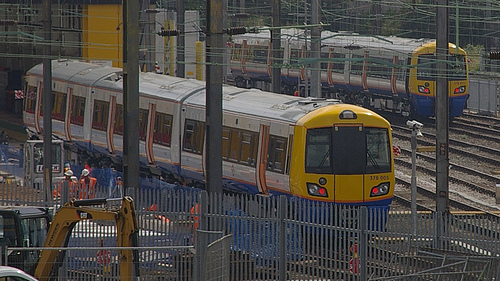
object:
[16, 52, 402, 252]
train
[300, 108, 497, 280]
tracks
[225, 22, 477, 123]
train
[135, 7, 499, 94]
background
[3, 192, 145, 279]
excavator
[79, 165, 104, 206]
men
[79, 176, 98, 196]
vest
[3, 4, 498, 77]
electric wires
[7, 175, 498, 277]
fence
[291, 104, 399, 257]
front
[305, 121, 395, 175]
windshield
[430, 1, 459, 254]
post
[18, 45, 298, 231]
grey cars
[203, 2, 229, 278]
bar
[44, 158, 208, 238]
people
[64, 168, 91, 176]
hard hats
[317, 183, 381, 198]
red headlights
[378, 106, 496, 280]
track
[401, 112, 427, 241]
cameras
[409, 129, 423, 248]
pole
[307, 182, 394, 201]
headlights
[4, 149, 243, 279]
trainyard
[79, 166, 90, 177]
hat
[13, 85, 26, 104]
sign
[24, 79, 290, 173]
windows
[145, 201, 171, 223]
worker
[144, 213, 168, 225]
safety vest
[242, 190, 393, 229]
bottom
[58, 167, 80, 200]
worker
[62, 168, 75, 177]
white helmet